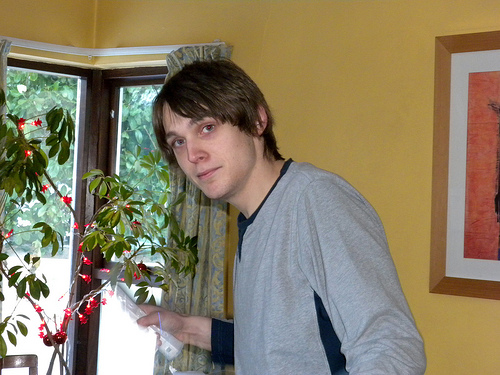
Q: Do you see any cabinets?
A: No, there are no cabinets.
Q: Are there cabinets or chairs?
A: No, there are no cabinets or chairs.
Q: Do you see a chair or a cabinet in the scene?
A: No, there are no cabinets or chairs.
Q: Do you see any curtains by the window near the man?
A: Yes, there is a curtain by the window.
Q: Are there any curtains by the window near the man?
A: Yes, there is a curtain by the window.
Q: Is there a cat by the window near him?
A: No, there is a curtain by the window.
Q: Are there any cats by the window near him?
A: No, there is a curtain by the window.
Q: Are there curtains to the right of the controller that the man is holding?
A: Yes, there is a curtain to the right of the controller.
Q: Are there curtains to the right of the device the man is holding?
A: Yes, there is a curtain to the right of the controller.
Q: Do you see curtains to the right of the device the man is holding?
A: Yes, there is a curtain to the right of the controller.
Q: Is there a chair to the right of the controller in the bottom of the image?
A: No, there is a curtain to the right of the controller.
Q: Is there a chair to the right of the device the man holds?
A: No, there is a curtain to the right of the controller.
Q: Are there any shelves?
A: No, there are no shelves.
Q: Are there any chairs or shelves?
A: No, there are no shelves or chairs.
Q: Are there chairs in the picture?
A: No, there are no chairs.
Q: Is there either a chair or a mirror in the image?
A: No, there are no chairs or mirrors.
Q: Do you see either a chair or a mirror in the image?
A: No, there are no chairs or mirrors.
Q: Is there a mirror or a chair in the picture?
A: No, there are no chairs or mirrors.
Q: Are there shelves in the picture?
A: No, there are no shelves.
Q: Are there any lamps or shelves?
A: No, there are no shelves or lamps.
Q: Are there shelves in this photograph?
A: No, there are no shelves.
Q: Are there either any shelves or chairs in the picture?
A: No, there are no shelves or chairs.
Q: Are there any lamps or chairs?
A: No, there are no chairs or lamps.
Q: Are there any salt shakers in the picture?
A: No, there are no salt shakers.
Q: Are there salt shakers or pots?
A: No, there are no salt shakers or pots.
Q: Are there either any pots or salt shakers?
A: No, there are no salt shakers or pots.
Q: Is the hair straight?
A: Yes, the hair is straight.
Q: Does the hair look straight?
A: Yes, the hair is straight.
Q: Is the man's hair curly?
A: No, the hair is straight.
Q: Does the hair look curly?
A: No, the hair is straight.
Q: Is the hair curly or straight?
A: The hair is straight.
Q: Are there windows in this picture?
A: Yes, there is a window.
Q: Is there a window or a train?
A: Yes, there is a window.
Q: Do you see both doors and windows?
A: No, there is a window but no doors.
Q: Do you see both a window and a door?
A: No, there is a window but no doors.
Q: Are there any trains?
A: No, there are no trains.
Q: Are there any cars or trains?
A: No, there are no trains or cars.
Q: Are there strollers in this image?
A: No, there are no strollers.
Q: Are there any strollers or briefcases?
A: No, there are no strollers or briefcases.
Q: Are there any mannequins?
A: No, there are no mannequins.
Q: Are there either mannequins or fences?
A: No, there are no mannequins or fences.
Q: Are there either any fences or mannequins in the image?
A: No, there are no mannequins or fences.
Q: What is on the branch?
A: The leaves are on the branch.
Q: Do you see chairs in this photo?
A: No, there are no chairs.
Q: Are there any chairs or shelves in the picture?
A: No, there are no chairs or shelves.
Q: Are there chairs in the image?
A: No, there are no chairs.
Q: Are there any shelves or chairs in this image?
A: No, there are no chairs or shelves.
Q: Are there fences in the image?
A: No, there are no fences.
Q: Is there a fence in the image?
A: No, there are no fences.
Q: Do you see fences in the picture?
A: No, there are no fences.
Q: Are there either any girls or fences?
A: No, there are no fences or girls.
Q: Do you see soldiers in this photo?
A: No, there are no soldiers.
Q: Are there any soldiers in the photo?
A: No, there are no soldiers.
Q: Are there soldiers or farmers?
A: No, there are no soldiers or farmers.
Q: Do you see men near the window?
A: Yes, there is a man near the window.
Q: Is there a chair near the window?
A: No, there is a man near the window.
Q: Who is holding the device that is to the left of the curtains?
A: The man is holding the controller.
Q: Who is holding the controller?
A: The man is holding the controller.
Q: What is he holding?
A: The man is holding the controller.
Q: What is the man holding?
A: The man is holding the controller.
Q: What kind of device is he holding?
A: The man is holding the controller.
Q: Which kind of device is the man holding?
A: The man is holding the controller.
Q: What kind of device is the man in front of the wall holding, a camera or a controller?
A: The man is holding a controller.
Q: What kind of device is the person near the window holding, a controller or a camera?
A: The man is holding a controller.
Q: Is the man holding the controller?
A: Yes, the man is holding the controller.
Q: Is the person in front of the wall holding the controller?
A: Yes, the man is holding the controller.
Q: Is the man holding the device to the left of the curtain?
A: Yes, the man is holding the controller.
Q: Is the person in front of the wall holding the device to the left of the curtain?
A: Yes, the man is holding the controller.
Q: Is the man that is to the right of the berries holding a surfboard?
A: No, the man is holding the controller.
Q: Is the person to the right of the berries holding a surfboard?
A: No, the man is holding the controller.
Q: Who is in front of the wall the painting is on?
A: The man is in front of the wall.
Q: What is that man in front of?
A: The man is in front of the wall.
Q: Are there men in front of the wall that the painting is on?
A: Yes, there is a man in front of the wall.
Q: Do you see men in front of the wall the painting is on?
A: Yes, there is a man in front of the wall.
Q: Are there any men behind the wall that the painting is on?
A: No, the man is in front of the wall.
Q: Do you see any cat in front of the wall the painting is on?
A: No, there is a man in front of the wall.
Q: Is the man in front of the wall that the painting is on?
A: Yes, the man is in front of the wall.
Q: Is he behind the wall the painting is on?
A: No, the man is in front of the wall.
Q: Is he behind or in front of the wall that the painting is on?
A: The man is in front of the wall.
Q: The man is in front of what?
A: The man is in front of the wall.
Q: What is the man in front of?
A: The man is in front of the wall.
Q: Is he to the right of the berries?
A: Yes, the man is to the right of the berries.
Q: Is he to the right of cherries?
A: No, the man is to the right of the berries.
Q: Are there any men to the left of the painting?
A: Yes, there is a man to the left of the painting.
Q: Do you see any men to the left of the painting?
A: Yes, there is a man to the left of the painting.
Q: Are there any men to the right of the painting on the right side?
A: No, the man is to the left of the painting.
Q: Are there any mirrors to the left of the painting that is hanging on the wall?
A: No, there is a man to the left of the painting.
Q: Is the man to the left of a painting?
A: Yes, the man is to the left of a painting.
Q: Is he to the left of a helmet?
A: No, the man is to the left of a painting.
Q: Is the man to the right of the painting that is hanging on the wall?
A: No, the man is to the left of the painting.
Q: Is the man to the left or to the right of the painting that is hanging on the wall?
A: The man is to the left of the painting.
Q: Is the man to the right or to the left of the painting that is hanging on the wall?
A: The man is to the left of the painting.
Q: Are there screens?
A: No, there are no screens.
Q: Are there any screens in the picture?
A: No, there are no screens.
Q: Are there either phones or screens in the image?
A: No, there are no screens or phones.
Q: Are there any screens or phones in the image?
A: No, there are no screens or phones.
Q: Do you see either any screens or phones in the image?
A: No, there are no screens or phones.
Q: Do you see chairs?
A: No, there are no chairs.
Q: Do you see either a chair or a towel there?
A: No, there are no chairs or towels.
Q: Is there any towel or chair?
A: No, there are no chairs or towels.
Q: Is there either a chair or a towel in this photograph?
A: No, there are no chairs or towels.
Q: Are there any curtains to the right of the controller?
A: Yes, there are curtains to the right of the controller.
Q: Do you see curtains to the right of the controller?
A: Yes, there are curtains to the right of the controller.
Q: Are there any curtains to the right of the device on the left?
A: Yes, there are curtains to the right of the controller.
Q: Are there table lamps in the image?
A: No, there are no table lamps.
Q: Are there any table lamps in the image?
A: No, there are no table lamps.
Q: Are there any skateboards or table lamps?
A: No, there are no table lamps or skateboards.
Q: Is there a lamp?
A: No, there are no lamps.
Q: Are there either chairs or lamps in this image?
A: No, there are no lamps or chairs.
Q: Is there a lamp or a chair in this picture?
A: No, there are no lamps or chairs.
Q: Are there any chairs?
A: No, there are no chairs.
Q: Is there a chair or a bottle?
A: No, there are no chairs or bottles.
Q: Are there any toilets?
A: No, there are no toilets.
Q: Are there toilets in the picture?
A: No, there are no toilets.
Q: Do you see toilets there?
A: No, there are no toilets.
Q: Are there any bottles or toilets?
A: No, there are no toilets or bottles.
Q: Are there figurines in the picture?
A: No, there are no figurines.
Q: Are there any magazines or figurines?
A: No, there are no figurines or magazines.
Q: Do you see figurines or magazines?
A: No, there are no figurines or magazines.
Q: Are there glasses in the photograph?
A: No, there are no glasses.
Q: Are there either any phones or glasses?
A: No, there are no glasses or phones.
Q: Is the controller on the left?
A: Yes, the controller is on the left of the image.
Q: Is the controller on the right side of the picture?
A: No, the controller is on the left of the image.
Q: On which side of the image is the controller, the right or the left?
A: The controller is on the left of the image.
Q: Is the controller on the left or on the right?
A: The controller is on the left of the image.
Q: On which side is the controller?
A: The controller is on the left of the image.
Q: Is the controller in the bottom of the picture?
A: Yes, the controller is in the bottom of the image.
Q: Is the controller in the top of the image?
A: No, the controller is in the bottom of the image.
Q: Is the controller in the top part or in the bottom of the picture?
A: The controller is in the bottom of the image.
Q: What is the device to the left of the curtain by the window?
A: The device is a controller.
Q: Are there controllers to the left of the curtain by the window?
A: Yes, there is a controller to the left of the curtain.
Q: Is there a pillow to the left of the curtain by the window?
A: No, there is a controller to the left of the curtain.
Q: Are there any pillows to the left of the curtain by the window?
A: No, there is a controller to the left of the curtain.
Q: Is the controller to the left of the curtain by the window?
A: Yes, the controller is to the left of the curtain.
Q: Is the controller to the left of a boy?
A: No, the controller is to the left of the curtain.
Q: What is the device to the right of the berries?
A: The device is a controller.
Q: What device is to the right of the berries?
A: The device is a controller.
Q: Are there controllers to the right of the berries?
A: Yes, there is a controller to the right of the berries.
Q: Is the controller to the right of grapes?
A: No, the controller is to the right of the berries.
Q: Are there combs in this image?
A: No, there are no combs.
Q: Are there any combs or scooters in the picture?
A: No, there are no combs or scooters.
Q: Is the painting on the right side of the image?
A: Yes, the painting is on the right of the image.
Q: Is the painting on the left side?
A: No, the painting is on the right of the image.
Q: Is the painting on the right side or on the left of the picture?
A: The painting is on the right of the image.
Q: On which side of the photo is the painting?
A: The painting is on the right of the image.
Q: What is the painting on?
A: The painting is on the wall.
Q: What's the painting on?
A: The painting is on the wall.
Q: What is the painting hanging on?
A: The painting is hanging on the wall.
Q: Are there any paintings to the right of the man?
A: Yes, there is a painting to the right of the man.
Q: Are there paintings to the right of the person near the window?
A: Yes, there is a painting to the right of the man.